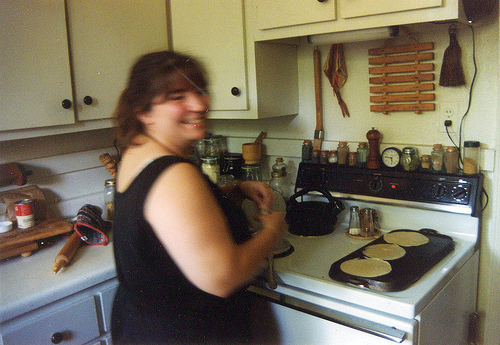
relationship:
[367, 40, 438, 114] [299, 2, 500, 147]
grate on wall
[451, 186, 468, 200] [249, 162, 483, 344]
knob on stove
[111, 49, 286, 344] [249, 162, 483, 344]
woman in front of stove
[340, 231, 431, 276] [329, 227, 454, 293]
cakes on griddle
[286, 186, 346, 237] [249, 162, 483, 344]
kettle atop stove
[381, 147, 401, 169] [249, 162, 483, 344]
timer atop stove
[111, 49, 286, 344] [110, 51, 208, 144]
woman has hair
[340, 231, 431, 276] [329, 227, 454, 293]
cakes atop griddle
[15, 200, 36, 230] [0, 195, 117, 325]
can atop counter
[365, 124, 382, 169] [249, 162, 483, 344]
grinder atop stove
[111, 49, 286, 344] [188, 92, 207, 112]
woman has nose